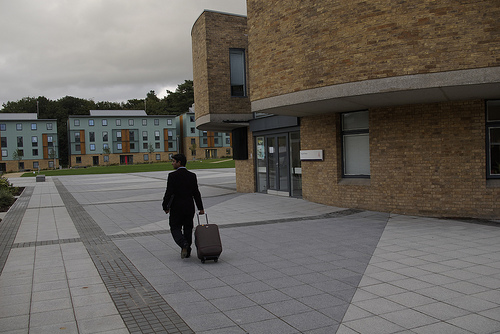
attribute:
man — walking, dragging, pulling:
[162, 153, 206, 257]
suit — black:
[163, 170, 205, 246]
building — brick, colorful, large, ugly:
[247, 2, 499, 223]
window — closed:
[338, 111, 373, 180]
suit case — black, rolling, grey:
[194, 211, 222, 259]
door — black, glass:
[265, 131, 292, 196]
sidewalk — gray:
[1, 172, 498, 333]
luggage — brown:
[196, 211, 221, 258]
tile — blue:
[347, 272, 381, 289]